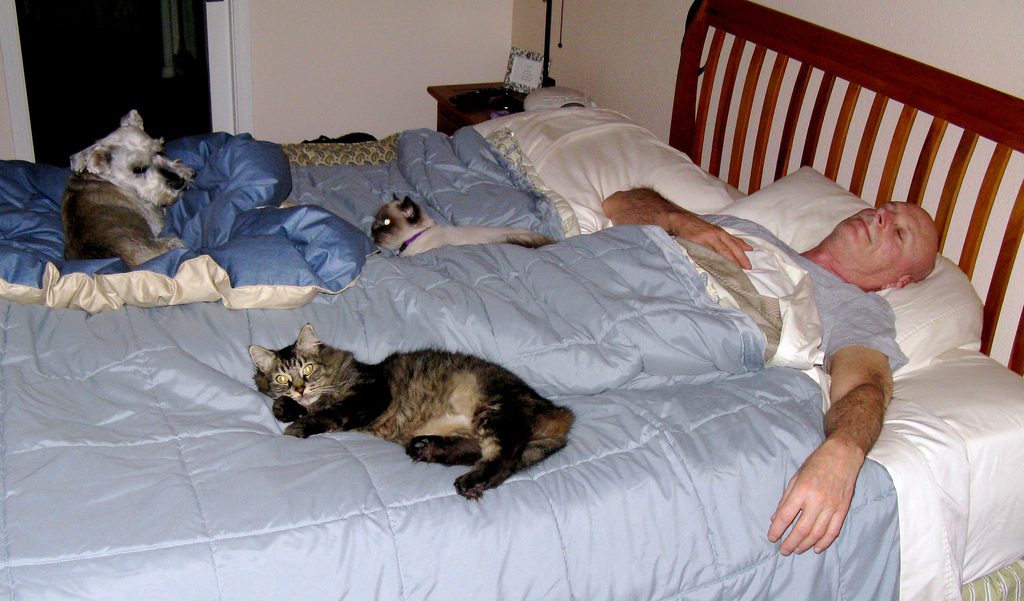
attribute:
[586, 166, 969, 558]
man — laying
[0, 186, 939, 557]
person — sleeping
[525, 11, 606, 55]
pull string — black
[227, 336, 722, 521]
cat — white, black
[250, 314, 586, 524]
cat — black, grey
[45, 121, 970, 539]
bed — white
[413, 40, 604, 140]
stand — wooden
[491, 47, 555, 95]
card — white, green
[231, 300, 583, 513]
cat — black, grey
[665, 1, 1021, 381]
headboard — wooden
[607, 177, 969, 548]
man — sleeping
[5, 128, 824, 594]
sheets — blue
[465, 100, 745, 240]
pillow — white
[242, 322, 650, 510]
dog — grey, white, fluffy